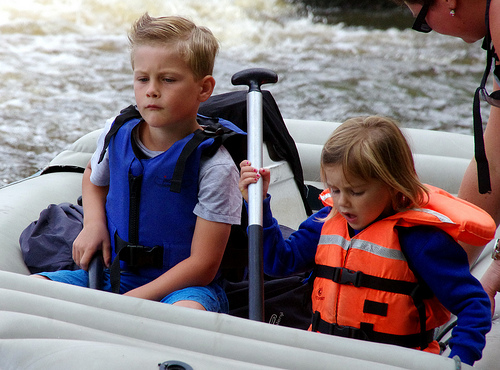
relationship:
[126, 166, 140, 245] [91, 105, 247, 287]
zipper on jacket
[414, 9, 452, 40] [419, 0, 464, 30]
glasses on face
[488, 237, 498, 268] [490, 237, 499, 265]
wristwatch has face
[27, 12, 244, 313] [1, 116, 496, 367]
boy sits in raft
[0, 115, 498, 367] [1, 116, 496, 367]
girl sits in raft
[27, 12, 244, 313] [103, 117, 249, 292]
boy wears blue jacket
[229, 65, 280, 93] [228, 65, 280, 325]
handle on paddle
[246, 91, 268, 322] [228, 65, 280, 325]
pole on paddle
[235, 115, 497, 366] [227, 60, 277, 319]
girl holds pole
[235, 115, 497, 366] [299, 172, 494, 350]
girl wears life vest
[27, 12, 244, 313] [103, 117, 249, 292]
boy wearing blue jacket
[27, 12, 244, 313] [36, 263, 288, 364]
boy in raft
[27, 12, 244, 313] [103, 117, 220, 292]
boy wearing blue jacket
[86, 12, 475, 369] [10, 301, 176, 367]
boy girl in raft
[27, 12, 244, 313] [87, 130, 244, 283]
boy wearing shirt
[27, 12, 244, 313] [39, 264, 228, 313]
boy wearing shorts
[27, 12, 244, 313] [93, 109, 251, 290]
boy wearing life jacket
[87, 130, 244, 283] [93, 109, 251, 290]
shirt under life jacket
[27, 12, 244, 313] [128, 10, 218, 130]
boy has head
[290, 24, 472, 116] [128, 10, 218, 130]
waves behind head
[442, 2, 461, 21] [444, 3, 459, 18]
ear with earrings